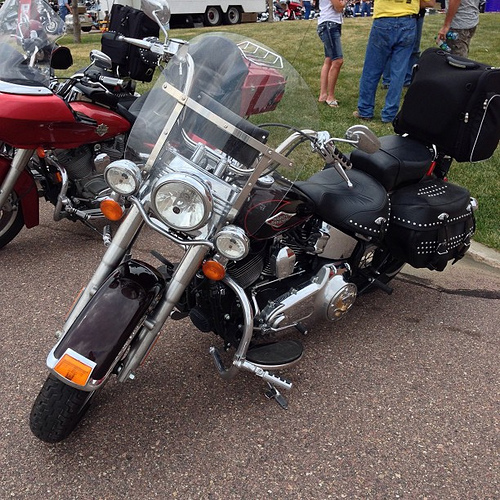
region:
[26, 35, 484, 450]
a silver and black motorcycle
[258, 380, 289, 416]
the kickstand on a motorcycle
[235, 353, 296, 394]
the footrest on a motorcycle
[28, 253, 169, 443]
the front wheel on a motorcycle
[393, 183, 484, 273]
the saddlebag on a motorcycle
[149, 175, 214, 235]
the headlight on a motorcycle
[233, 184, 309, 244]
the gas-tank on a motorcycle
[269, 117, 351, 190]
the left handlebar on a motorcycle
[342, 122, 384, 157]
the mirror on a motorcycle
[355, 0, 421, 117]
a man wearing jeans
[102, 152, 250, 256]
Headlights in the photo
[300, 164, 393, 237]
A motor cycle seat in the photo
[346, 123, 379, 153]
Motor cycle side mirror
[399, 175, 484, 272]
A bag on the motor cycle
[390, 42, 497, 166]
A suitcase on the motor cycle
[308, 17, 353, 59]
Shorts in the photo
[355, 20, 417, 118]
Blue jeans in the photo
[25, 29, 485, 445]
A motorcycle in the photo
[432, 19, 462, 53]
Cans in the photo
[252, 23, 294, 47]
Grass in the photo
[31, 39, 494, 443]
Harley Davidson motorcycle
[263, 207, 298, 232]
Harley Davidson bike logo plate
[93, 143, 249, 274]
Motorcycle set of headlights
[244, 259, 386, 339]
Motorcycle chain assembly cover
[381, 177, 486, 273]
Decorative side bags for storage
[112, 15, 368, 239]
Motorcycle steering assembly with windshield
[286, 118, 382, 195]
Throttle with braking mechanism as well as side mirror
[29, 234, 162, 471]
Motorcycle front tire with reflector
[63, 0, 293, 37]
Bottom portion of food truck for event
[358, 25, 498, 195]
Second rider seat with backrest that is also for storage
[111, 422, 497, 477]
The ground is made of asphalt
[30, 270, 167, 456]
The front tire of a motorcycle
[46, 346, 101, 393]
The front reflector of the motorcycle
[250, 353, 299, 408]
The kickstand of the motorcycle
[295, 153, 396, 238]
The seat of the motorcycle is black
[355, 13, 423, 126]
The man is wearing blue jeans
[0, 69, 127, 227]
The color of the motorcycle is red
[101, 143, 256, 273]
The head lights of the motorcycle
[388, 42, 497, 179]
Luggage sitting on the back of the motorcycle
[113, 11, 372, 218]
The handle bars on the motorcycle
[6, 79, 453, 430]
dark maroon frame on motorcycle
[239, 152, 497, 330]
black beaded on side of motorcycle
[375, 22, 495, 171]
black suitcase behind seat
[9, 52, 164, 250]
red framed motorcyle with chrome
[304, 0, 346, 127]
person wearing blue jean shorts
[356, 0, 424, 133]
person wearing yellow shirt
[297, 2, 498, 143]
people standing on the grass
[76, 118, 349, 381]
chrome parts on motorcycle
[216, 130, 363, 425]
black foot rest on motorcycle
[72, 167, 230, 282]
orange reflector lights on front of motorcycle